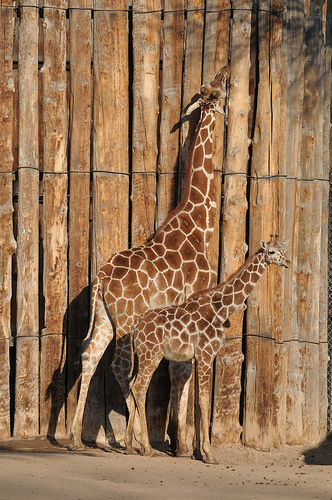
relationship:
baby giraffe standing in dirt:
[114, 230, 293, 460] [0, 437, 331, 498]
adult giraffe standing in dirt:
[68, 65, 230, 456] [0, 437, 331, 498]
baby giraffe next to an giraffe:
[114, 230, 293, 433] [87, 64, 249, 406]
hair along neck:
[184, 242, 266, 300] [190, 248, 271, 312]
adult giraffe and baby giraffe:
[68, 65, 230, 456] [124, 234, 290, 464]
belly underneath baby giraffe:
[163, 350, 192, 363] [124, 234, 290, 464]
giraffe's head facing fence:
[186, 75, 244, 119] [7, 15, 327, 102]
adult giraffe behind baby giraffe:
[68, 65, 230, 456] [124, 234, 290, 464]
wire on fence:
[3, 3, 285, 18] [0, 0, 329, 453]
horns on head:
[268, 234, 279, 243] [259, 228, 292, 271]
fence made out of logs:
[5, 18, 112, 264] [258, 7, 274, 234]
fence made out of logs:
[5, 18, 112, 264] [131, 1, 157, 224]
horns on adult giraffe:
[198, 84, 222, 101] [68, 65, 230, 456]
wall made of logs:
[1, 1, 320, 444] [43, 13, 128, 171]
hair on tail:
[126, 243, 293, 460] [70, 280, 109, 361]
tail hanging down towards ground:
[56, 275, 99, 399] [1, 441, 330, 499]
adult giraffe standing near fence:
[68, 65, 230, 456] [0, 0, 329, 453]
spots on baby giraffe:
[197, 300, 216, 321] [114, 230, 293, 460]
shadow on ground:
[300, 431, 330, 467] [1, 441, 330, 499]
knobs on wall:
[217, 349, 248, 367] [1, 1, 320, 444]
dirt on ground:
[218, 455, 295, 486] [1, 441, 330, 499]